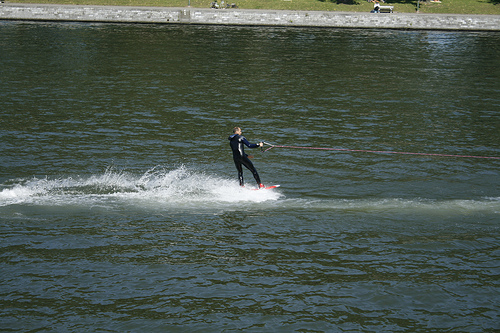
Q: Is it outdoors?
A: Yes, it is outdoors.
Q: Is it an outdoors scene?
A: Yes, it is outdoors.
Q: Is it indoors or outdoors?
A: It is outdoors.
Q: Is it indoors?
A: No, it is outdoors.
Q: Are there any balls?
A: No, there are no balls.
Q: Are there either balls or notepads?
A: No, there are no balls or notepads.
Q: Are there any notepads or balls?
A: No, there are no balls or notepads.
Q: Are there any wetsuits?
A: Yes, there is a wetsuit.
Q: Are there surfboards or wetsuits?
A: Yes, there is a wetsuit.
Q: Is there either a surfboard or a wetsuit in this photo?
A: Yes, there is a wetsuit.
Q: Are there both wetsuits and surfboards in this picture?
A: No, there is a wetsuit but no surfboards.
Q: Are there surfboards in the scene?
A: No, there are no surfboards.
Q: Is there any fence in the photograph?
A: No, there are no fences.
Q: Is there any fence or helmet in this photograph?
A: No, there are no fences or helmets.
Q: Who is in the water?
A: The man is in the water.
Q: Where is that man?
A: The man is in the water.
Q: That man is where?
A: The man is in the water.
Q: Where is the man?
A: The man is in the water.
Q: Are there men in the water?
A: Yes, there is a man in the water.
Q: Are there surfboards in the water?
A: No, there is a man in the water.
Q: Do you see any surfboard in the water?
A: No, there is a man in the water.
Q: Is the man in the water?
A: Yes, the man is in the water.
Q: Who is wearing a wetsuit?
A: The man is wearing a wetsuit.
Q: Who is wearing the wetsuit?
A: The man is wearing a wetsuit.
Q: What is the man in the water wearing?
A: The man is wearing a wetsuit.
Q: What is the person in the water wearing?
A: The man is wearing a wetsuit.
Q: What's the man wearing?
A: The man is wearing a wetsuit.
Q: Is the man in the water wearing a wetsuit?
A: Yes, the man is wearing a wetsuit.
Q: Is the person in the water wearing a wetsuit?
A: Yes, the man is wearing a wetsuit.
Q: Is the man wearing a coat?
A: No, the man is wearing a wetsuit.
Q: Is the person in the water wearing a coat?
A: No, the man is wearing a wetsuit.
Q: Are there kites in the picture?
A: No, there are no kites.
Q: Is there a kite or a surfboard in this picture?
A: No, there are no kites or surfboards.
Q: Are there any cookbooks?
A: No, there are no cookbooks.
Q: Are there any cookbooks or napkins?
A: No, there are no cookbooks or napkins.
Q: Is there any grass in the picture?
A: Yes, there is grass.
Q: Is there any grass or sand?
A: Yes, there is grass.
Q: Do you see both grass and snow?
A: No, there is grass but no snow.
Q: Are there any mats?
A: No, there are no mats.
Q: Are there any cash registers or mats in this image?
A: No, there are no mats or cash registers.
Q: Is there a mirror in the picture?
A: No, there are no mirrors.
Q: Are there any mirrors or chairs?
A: No, there are no mirrors or chairs.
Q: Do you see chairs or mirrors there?
A: No, there are no mirrors or chairs.